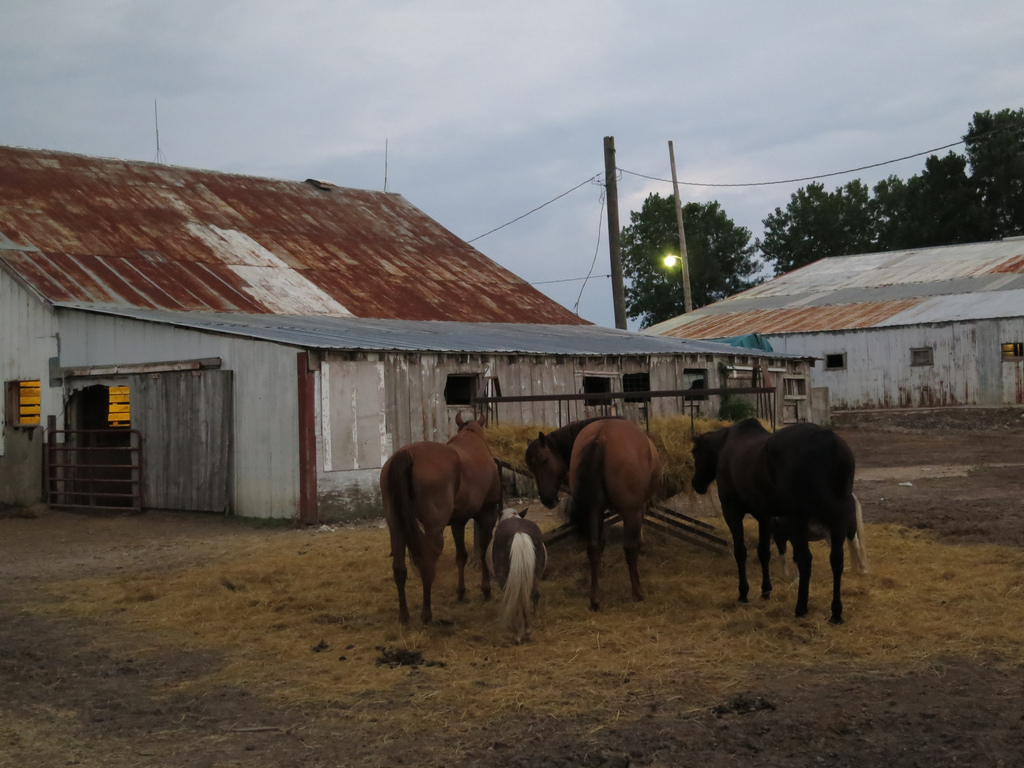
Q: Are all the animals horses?
A: Yes, all the animals are horses.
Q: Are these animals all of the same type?
A: Yes, all the animals are horses.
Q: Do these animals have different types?
A: No, all the animals are horses.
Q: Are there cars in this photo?
A: No, there are no cars.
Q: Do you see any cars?
A: No, there are no cars.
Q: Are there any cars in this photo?
A: No, there are no cars.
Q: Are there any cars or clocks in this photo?
A: No, there are no cars or clocks.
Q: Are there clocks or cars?
A: No, there are no cars or clocks.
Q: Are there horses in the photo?
A: Yes, there is a horse.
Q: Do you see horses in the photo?
A: Yes, there is a horse.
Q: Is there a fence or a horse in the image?
A: Yes, there is a horse.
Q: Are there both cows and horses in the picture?
A: No, there is a horse but no cows.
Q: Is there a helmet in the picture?
A: No, there are no helmets.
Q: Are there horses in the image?
A: Yes, there is a horse.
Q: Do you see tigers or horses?
A: Yes, there is a horse.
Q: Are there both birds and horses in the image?
A: No, there is a horse but no birds.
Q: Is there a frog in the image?
A: No, there are no frogs.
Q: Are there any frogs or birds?
A: No, there are no frogs or birds.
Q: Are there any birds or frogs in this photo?
A: No, there are no frogs or birds.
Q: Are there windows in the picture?
A: Yes, there is a window.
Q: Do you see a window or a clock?
A: Yes, there is a window.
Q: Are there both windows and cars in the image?
A: No, there is a window but no cars.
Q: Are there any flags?
A: No, there are no flags.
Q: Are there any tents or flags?
A: No, there are no flags or tents.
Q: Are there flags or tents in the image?
A: No, there are no flags or tents.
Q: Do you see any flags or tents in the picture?
A: No, there are no flags or tents.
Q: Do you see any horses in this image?
A: Yes, there is a horse.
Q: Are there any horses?
A: Yes, there is a horse.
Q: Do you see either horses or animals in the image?
A: Yes, there is a horse.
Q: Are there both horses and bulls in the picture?
A: No, there is a horse but no bulls.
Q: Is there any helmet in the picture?
A: No, there are no helmets.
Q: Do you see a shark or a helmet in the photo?
A: No, there are no helmets or sharks.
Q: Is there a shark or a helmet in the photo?
A: No, there are no helmets or sharks.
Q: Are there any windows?
A: Yes, there is a window.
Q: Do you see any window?
A: Yes, there is a window.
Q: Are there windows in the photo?
A: Yes, there is a window.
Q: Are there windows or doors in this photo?
A: Yes, there is a window.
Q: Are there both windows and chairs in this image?
A: No, there is a window but no chairs.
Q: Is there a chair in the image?
A: No, there are no chairs.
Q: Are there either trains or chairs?
A: No, there are no chairs or trains.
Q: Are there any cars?
A: No, there are no cars.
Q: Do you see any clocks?
A: No, there are no clocks.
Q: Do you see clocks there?
A: No, there are no clocks.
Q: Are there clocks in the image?
A: No, there are no clocks.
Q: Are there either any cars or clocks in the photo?
A: No, there are no clocks or cars.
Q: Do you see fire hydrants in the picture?
A: No, there are no fire hydrants.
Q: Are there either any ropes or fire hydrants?
A: No, there are no fire hydrants or ropes.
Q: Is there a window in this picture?
A: Yes, there is a window.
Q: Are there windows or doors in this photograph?
A: Yes, there is a window.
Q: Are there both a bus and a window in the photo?
A: No, there is a window but no buses.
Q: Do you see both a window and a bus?
A: No, there is a window but no buses.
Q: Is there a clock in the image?
A: No, there are no clocks.